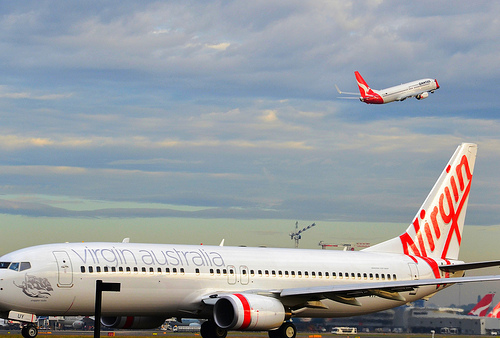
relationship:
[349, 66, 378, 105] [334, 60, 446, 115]
tail of aircraft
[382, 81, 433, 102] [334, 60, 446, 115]
fuselage of aircraft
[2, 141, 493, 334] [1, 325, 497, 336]
virgin aircraft on ground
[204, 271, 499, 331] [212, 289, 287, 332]
airplane wing with engine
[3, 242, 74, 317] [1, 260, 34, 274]
cockpit has windows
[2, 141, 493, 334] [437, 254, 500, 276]
virgin aircraft has horizontal stabilize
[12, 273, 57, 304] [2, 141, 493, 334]
logo on virgin aircraft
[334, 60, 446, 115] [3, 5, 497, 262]
aircraft in sky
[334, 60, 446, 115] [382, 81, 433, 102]
aircraft has fuselage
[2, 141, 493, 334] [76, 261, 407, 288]
virgin aircraft has windows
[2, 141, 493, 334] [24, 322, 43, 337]
virgin aircraft has front wheel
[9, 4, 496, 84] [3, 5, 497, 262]
clouds are in sky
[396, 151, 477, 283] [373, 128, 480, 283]
virgin on tail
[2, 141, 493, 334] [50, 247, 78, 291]
virgin aircraft has door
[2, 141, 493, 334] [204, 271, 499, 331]
virgin aircraft has airplane wing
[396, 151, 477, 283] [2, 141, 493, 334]
virgin on virgin aircraft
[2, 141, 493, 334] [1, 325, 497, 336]
virgin aircraft sitting on tarmac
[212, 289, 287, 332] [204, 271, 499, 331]
engine under airplane wing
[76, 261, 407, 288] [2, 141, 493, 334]
windows are on virgin aircraft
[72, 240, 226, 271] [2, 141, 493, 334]
virgin australia log on virgin aircraft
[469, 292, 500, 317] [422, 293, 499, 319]
tails of red planes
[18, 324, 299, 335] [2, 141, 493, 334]
tires under virgin aircraft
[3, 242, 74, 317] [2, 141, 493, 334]
cockpit in front of virgin aircraft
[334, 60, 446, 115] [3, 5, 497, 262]
aircraft taking off into sky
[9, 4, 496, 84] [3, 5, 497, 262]
clouds in sky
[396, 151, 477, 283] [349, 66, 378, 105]
virgin on tail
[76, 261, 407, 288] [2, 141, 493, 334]
windows on virgin aircraft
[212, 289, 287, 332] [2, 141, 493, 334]
engine of virgin aircraft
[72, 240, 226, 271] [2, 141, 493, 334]
virgin australia log on side of virgin aircraft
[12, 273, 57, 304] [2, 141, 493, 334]
logo on side of virgin aircraft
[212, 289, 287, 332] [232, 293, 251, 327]
engine has stripe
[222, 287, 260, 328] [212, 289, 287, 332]
stripe on engine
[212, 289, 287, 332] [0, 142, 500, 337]
engine on virgin aircraft